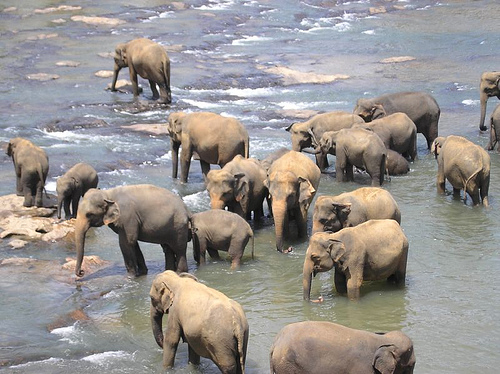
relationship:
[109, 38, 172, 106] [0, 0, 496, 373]
elephant standing in water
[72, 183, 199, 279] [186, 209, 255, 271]
elephant next to elephant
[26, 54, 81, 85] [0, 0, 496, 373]
rocks in water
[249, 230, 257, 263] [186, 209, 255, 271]
tail on elephant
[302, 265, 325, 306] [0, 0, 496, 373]
trunk in water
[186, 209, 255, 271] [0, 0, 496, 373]
elephant in water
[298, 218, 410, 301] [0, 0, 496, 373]
elephant knee deep in water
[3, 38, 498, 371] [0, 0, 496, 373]
elephants in water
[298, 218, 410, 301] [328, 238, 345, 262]
elephant has ear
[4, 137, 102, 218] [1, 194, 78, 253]
elephants standing on rock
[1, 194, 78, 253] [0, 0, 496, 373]
rock in water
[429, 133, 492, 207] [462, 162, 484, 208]
elephant has tail